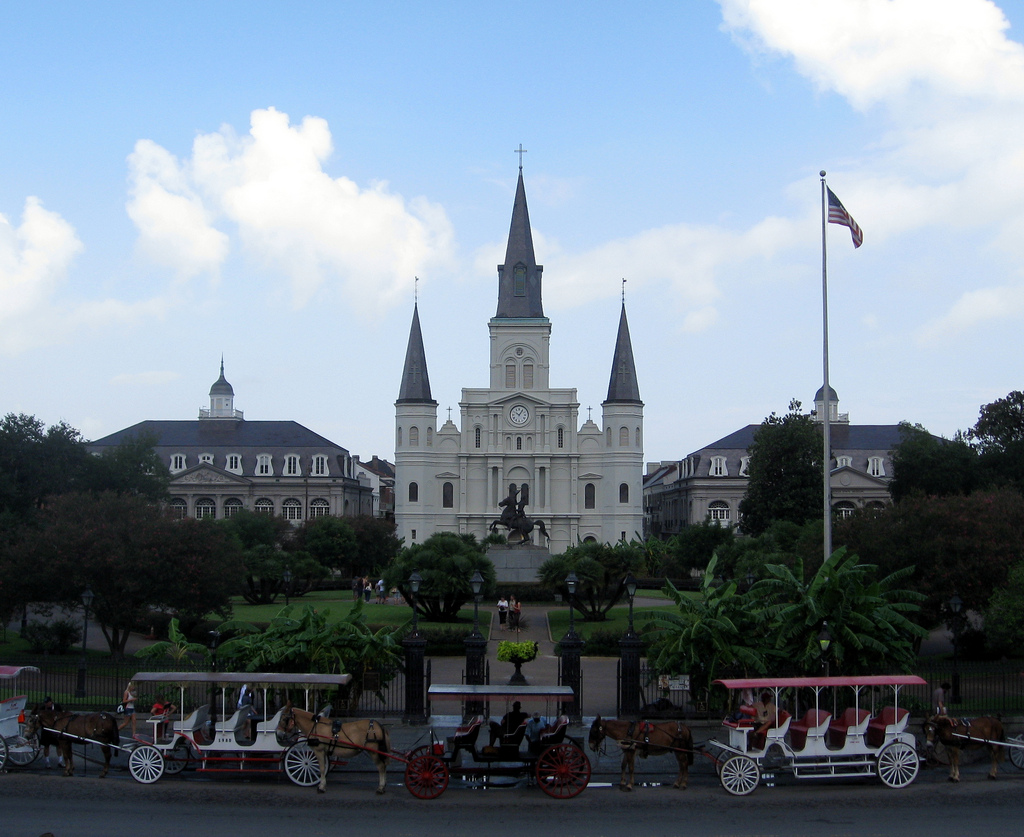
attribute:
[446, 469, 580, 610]
statue — big